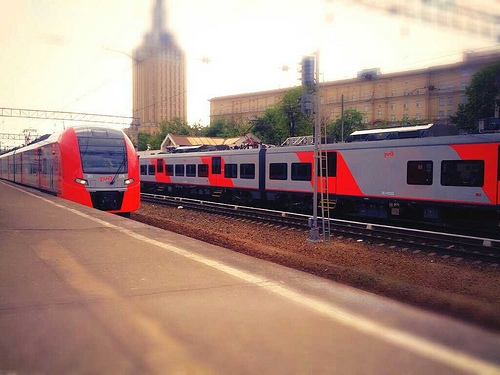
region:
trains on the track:
[6, 130, 488, 266]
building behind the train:
[206, 70, 491, 134]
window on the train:
[76, 139, 125, 170]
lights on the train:
[70, 178, 140, 192]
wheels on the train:
[153, 191, 253, 205]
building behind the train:
[116, 3, 192, 129]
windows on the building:
[333, 83, 411, 98]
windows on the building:
[174, 61, 181, 100]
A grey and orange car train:
[265, 140, 336, 209]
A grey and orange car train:
[158, 142, 254, 197]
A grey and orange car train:
[22, 128, 137, 205]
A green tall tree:
[265, 68, 315, 143]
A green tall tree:
[326, 93, 386, 158]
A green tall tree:
[466, 31, 496, 122]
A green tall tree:
[142, 113, 223, 143]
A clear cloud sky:
[25, 20, 85, 81]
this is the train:
[281, 135, 465, 204]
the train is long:
[347, 142, 444, 203]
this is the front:
[65, 132, 135, 207]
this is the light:
[121, 175, 141, 189]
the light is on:
[117, 175, 136, 191]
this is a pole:
[302, 119, 339, 229]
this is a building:
[132, 40, 187, 117]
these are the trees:
[261, 98, 297, 128]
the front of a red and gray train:
[50, 109, 158, 226]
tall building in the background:
[115, 7, 201, 272]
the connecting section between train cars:
[227, 144, 294, 210]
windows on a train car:
[267, 160, 315, 185]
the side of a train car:
[276, 150, 479, 193]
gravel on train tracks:
[187, 211, 409, 273]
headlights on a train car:
[65, 175, 140, 200]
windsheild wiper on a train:
[105, 138, 134, 190]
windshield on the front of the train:
[65, 125, 140, 177]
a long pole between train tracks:
[292, 40, 352, 249]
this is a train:
[46, 130, 152, 206]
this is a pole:
[304, 35, 331, 247]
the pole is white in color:
[295, 129, 326, 189]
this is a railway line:
[349, 201, 416, 255]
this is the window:
[408, 162, 432, 181]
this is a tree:
[452, 68, 498, 105]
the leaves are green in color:
[277, 103, 298, 118]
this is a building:
[350, 66, 439, 89]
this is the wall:
[361, 85, 411, 108]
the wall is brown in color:
[363, 82, 396, 97]